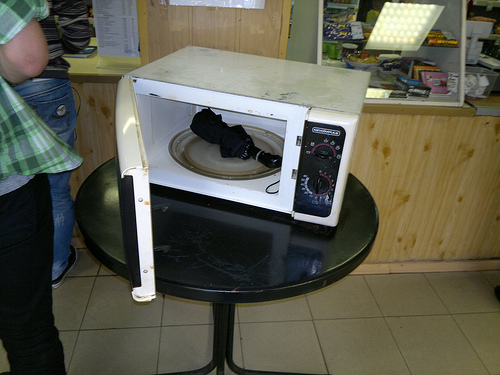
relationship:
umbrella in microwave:
[183, 112, 284, 172] [116, 31, 363, 250]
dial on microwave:
[306, 136, 340, 166] [116, 31, 363, 250]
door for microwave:
[108, 75, 164, 299] [116, 31, 363, 250]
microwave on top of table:
[116, 31, 363, 250] [82, 175, 327, 375]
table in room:
[82, 175, 327, 375] [0, 5, 499, 374]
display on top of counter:
[321, 10, 485, 103] [360, 110, 500, 130]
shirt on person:
[3, 7, 69, 193] [1, 2, 67, 374]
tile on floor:
[385, 317, 464, 375] [74, 254, 496, 367]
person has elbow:
[1, 2, 67, 374] [15, 48, 60, 83]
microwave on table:
[116, 31, 363, 250] [82, 175, 327, 375]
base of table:
[199, 301, 256, 374] [82, 175, 327, 375]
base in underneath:
[199, 301, 256, 374] [157, 302, 305, 373]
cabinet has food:
[321, 10, 485, 103] [331, 6, 450, 91]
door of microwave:
[108, 75, 164, 299] [116, 31, 363, 250]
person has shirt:
[1, 2, 67, 374] [3, 7, 69, 193]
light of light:
[123, 117, 136, 133] [123, 115, 136, 135]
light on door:
[123, 117, 136, 133] [108, 75, 164, 299]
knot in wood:
[393, 190, 424, 217] [70, 78, 488, 258]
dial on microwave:
[303, 172, 334, 202] [116, 31, 363, 250]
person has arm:
[1, 2, 67, 374] [2, 12, 52, 83]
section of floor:
[245, 274, 490, 374] [74, 254, 496, 367]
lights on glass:
[364, 2, 440, 52] [312, 1, 464, 107]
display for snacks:
[321, 10, 485, 103] [331, 6, 450, 91]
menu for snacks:
[93, 7, 144, 62] [331, 6, 450, 91]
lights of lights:
[364, 2, 440, 52] [378, 6, 423, 49]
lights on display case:
[364, 2, 440, 52] [321, 10, 485, 103]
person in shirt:
[1, 2, 67, 374] [3, 7, 69, 193]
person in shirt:
[26, 9, 102, 287] [28, 2, 92, 70]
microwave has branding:
[116, 31, 363, 250] [307, 127, 347, 142]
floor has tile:
[74, 254, 496, 367] [385, 317, 464, 375]